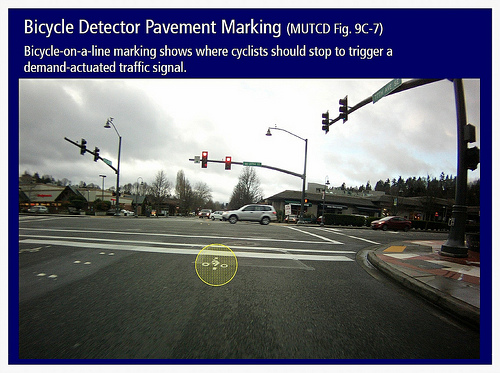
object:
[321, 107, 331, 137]
traffic light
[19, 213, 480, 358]
road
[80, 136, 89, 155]
traffic light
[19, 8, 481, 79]
ad banner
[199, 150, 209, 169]
light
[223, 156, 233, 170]
light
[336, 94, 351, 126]
traffic light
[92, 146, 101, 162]
traffic light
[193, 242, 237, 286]
circle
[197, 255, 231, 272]
cyclist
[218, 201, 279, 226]
vehicle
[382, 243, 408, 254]
spot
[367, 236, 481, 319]
sidewalk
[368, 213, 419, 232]
vehicle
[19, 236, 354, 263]
marking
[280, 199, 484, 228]
wall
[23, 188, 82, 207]
wall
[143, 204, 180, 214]
wall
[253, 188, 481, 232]
building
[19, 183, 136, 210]
building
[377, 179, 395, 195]
leaves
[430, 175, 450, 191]
leaves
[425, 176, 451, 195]
leaves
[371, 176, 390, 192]
leaves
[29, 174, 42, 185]
leaves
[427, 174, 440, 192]
tree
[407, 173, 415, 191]
tree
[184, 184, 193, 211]
leaves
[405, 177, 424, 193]
leaves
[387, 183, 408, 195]
leaves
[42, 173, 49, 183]
tree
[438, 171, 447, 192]
tree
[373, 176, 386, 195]
tree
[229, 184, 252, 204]
leaves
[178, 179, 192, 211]
leaves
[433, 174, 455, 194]
leaves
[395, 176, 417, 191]
leaves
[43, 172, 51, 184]
leaves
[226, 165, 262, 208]
tree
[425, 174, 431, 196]
tree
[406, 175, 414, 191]
tree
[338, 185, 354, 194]
leaves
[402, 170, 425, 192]
leaves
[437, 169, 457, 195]
leaves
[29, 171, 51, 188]
leaves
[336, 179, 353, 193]
tree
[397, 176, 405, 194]
tree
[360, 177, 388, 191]
leaves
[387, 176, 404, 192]
leaves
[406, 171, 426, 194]
leaves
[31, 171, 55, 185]
leaves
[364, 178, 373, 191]
tree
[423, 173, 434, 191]
tree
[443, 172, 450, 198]
tree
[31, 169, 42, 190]
tree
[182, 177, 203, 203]
leaves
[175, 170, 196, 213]
tree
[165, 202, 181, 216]
tree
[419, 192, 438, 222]
tree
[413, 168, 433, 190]
leaves